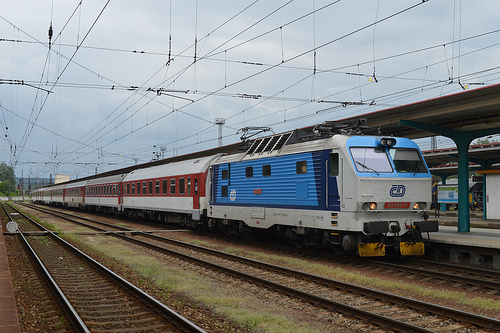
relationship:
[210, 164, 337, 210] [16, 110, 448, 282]
paint on train